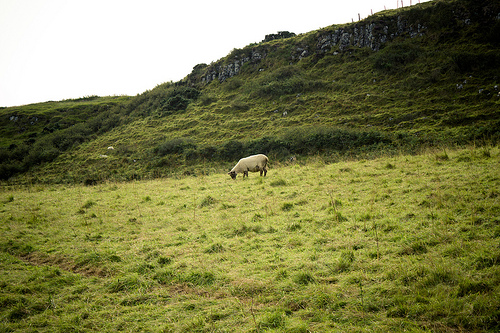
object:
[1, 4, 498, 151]
hillside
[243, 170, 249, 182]
legs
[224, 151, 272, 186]
sheep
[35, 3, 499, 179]
grass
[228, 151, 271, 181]
lamb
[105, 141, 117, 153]
sheep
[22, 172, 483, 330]
grass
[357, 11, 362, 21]
post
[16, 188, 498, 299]
field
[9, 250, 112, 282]
dirt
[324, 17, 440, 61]
cliff.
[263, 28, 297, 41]
tree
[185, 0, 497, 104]
cliff face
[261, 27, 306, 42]
bush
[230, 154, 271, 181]
animal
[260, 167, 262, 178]
legs